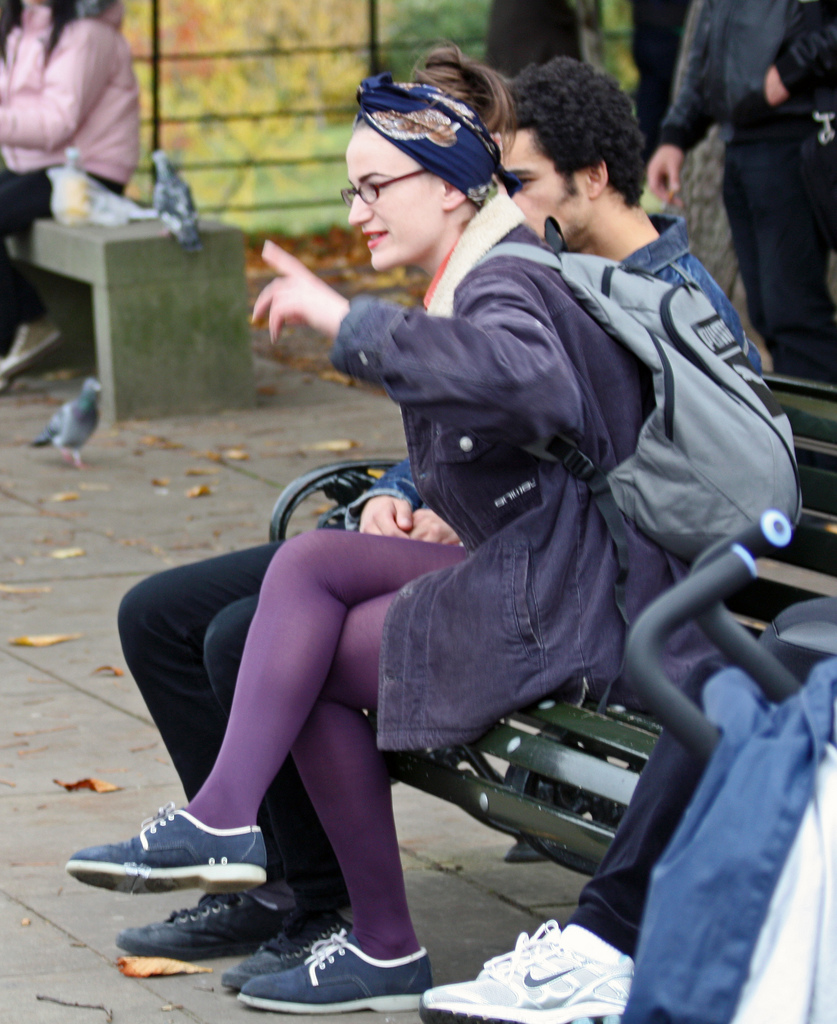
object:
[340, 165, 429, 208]
glasses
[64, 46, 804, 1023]
woman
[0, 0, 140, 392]
lady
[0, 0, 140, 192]
coat